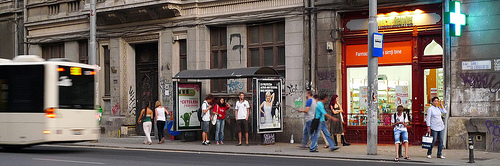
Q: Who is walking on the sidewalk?
A: People.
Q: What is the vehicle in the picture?
A: A bus.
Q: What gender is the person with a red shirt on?
A: Female.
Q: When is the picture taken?
A: Daytime.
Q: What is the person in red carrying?
A: A purse.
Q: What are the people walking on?
A: A sidewalk.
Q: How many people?
A: Eleven.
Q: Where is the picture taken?
A: On a city street.